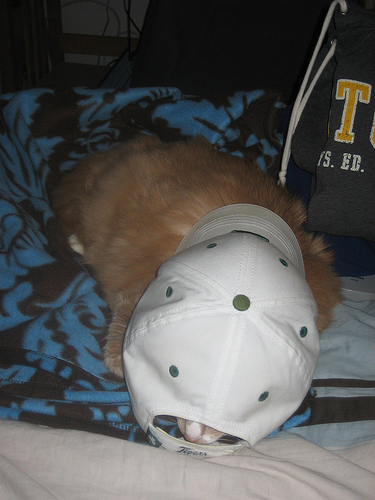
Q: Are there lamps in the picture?
A: No, there are no lamps.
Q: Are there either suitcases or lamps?
A: No, there are no lamps or suitcases.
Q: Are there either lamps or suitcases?
A: No, there are no lamps or suitcases.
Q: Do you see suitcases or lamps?
A: No, there are no lamps or suitcases.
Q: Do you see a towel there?
A: No, there are no towels.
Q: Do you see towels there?
A: No, there are no towels.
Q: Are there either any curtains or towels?
A: No, there are no towels or curtains.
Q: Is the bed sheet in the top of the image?
A: No, the bed sheet is in the bottom of the image.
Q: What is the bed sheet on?
A: The bed sheet is on the bed.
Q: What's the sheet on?
A: The bed sheet is on the bed.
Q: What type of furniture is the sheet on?
A: The sheet is on the bed.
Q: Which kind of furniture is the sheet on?
A: The sheet is on the bed.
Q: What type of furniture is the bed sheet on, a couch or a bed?
A: The bed sheet is on a bed.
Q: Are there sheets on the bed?
A: Yes, there is a sheet on the bed.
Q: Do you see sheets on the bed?
A: Yes, there is a sheet on the bed.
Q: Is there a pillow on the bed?
A: No, there is a sheet on the bed.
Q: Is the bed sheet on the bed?
A: Yes, the bed sheet is on the bed.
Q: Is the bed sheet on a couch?
A: No, the bed sheet is on the bed.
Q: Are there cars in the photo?
A: No, there are no cars.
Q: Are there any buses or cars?
A: No, there are no cars or buses.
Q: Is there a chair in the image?
A: No, there are no chairs.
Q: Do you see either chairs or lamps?
A: No, there are no chairs or lamps.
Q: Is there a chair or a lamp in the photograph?
A: No, there are no chairs or lamps.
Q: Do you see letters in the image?
A: Yes, there are letters.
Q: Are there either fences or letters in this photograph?
A: Yes, there are letters.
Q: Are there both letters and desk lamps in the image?
A: No, there are letters but no desk lamps.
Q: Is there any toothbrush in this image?
A: No, there are no toothbrushes.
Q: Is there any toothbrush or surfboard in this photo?
A: No, there are no toothbrushes or surfboards.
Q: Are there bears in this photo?
A: No, there are no bears.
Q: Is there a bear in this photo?
A: No, there are no bears.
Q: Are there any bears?
A: No, there are no bears.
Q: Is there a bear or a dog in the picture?
A: No, there are no bears or dogs.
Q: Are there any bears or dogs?
A: No, there are no bears or dogs.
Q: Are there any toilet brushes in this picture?
A: No, there are no toilet brushes.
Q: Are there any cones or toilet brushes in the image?
A: No, there are no toilet brushes or cones.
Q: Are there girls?
A: No, there are no girls.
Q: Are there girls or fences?
A: No, there are no girls or fences.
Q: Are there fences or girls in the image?
A: No, there are no girls or fences.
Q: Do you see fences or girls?
A: No, there are no girls or fences.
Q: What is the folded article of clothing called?
A: The clothing item is a shirt.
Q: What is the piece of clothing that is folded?
A: The clothing item is a shirt.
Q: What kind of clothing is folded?
A: The clothing is a shirt.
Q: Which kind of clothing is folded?
A: The clothing is a shirt.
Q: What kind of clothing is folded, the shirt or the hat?
A: The shirt is folded.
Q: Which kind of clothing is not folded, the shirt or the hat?
A: The hat is not folded.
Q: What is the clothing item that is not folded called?
A: The clothing item is a hat.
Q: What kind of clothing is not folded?
A: The clothing is a hat.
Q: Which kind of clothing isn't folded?
A: The clothing is a hat.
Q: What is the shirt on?
A: The shirt is on the bed.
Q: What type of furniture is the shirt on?
A: The shirt is on the bed.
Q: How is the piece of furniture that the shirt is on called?
A: The piece of furniture is a bed.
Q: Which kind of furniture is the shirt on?
A: The shirt is on the bed.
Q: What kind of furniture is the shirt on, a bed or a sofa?
A: The shirt is on a bed.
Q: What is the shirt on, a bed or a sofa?
A: The shirt is on a bed.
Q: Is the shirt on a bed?
A: Yes, the shirt is on a bed.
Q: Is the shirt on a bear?
A: No, the shirt is on a bed.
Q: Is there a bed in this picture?
A: Yes, there is a bed.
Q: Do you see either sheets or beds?
A: Yes, there is a bed.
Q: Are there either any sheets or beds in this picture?
A: Yes, there is a bed.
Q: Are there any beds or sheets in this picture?
A: Yes, there is a bed.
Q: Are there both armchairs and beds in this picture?
A: No, there is a bed but no armchairs.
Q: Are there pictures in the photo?
A: No, there are no pictures.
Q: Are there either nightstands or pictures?
A: No, there are no pictures or nightstands.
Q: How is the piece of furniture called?
A: The piece of furniture is a bed.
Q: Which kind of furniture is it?
A: The piece of furniture is a bed.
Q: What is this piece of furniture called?
A: This is a bed.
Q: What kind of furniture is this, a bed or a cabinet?
A: This is a bed.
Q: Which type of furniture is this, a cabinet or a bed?
A: This is a bed.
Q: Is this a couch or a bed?
A: This is a bed.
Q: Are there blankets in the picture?
A: Yes, there is a blanket.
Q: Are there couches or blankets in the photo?
A: Yes, there is a blanket.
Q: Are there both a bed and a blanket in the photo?
A: Yes, there are both a blanket and a bed.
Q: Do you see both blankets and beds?
A: Yes, there are both a blanket and a bed.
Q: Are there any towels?
A: No, there are no towels.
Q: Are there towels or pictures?
A: No, there are no towels or pictures.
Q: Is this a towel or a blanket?
A: This is a blanket.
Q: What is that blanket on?
A: The blanket is on the bed.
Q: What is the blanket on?
A: The blanket is on the bed.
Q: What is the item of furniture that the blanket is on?
A: The piece of furniture is a bed.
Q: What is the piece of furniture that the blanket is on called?
A: The piece of furniture is a bed.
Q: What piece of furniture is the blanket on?
A: The blanket is on the bed.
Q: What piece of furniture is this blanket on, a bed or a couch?
A: The blanket is on a bed.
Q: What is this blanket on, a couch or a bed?
A: The blanket is on a bed.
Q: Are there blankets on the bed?
A: Yes, there is a blanket on the bed.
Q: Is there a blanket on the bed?
A: Yes, there is a blanket on the bed.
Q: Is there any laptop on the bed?
A: No, there is a blanket on the bed.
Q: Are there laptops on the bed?
A: No, there is a blanket on the bed.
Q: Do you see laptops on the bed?
A: No, there is a blanket on the bed.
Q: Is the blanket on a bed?
A: Yes, the blanket is on a bed.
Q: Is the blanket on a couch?
A: No, the blanket is on a bed.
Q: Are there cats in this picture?
A: Yes, there is a cat.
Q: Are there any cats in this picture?
A: Yes, there is a cat.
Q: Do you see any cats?
A: Yes, there is a cat.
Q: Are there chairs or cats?
A: Yes, there is a cat.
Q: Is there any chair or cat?
A: Yes, there is a cat.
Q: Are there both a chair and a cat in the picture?
A: No, there is a cat but no chairs.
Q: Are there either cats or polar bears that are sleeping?
A: Yes, the cat is sleeping.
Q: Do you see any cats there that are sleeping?
A: Yes, there is a cat that is sleeping.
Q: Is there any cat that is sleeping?
A: Yes, there is a cat that is sleeping.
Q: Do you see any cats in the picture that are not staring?
A: Yes, there is a cat that is sleeping .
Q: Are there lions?
A: No, there are no lions.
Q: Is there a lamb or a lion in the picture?
A: No, there are no lions or lambs.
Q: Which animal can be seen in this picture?
A: The animal is a cat.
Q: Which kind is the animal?
A: The animal is a cat.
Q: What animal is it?
A: The animal is a cat.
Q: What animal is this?
A: This is a cat.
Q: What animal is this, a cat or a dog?
A: This is a cat.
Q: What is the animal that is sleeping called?
A: The animal is a cat.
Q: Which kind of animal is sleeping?
A: The animal is a cat.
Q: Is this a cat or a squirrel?
A: This is a cat.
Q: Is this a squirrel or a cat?
A: This is a cat.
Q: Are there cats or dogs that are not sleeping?
A: No, there is a cat but it is sleeping.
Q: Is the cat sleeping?
A: Yes, the cat is sleeping.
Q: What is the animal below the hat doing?
A: The cat is sleeping.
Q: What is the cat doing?
A: The cat is sleeping.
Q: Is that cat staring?
A: No, the cat is sleeping.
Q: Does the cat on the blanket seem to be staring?
A: No, the cat is sleeping.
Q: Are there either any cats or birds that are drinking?
A: No, there is a cat but it is sleeping.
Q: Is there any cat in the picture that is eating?
A: No, there is a cat but it is sleeping.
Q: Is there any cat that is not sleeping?
A: No, there is a cat but it is sleeping.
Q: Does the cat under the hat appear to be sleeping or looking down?
A: The cat is sleeping.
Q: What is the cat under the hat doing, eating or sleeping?
A: The cat is sleeping.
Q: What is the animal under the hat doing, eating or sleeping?
A: The cat is sleeping.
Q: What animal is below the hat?
A: The animal is a cat.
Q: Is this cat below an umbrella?
A: No, the cat is below the hat.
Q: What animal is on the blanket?
A: The cat is on the blanket.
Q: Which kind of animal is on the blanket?
A: The animal is a cat.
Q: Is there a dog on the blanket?
A: No, there is a cat on the blanket.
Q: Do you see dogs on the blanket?
A: No, there is a cat on the blanket.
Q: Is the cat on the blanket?
A: Yes, the cat is on the blanket.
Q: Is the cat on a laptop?
A: No, the cat is on the blanket.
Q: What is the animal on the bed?
A: The animal is a cat.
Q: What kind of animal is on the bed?
A: The animal is a cat.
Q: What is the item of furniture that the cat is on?
A: The piece of furniture is a bed.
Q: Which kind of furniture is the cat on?
A: The cat is on the bed.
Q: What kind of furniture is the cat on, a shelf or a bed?
A: The cat is on a bed.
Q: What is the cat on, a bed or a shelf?
A: The cat is on a bed.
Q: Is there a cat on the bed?
A: Yes, there is a cat on the bed.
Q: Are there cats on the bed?
A: Yes, there is a cat on the bed.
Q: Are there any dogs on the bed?
A: No, there is a cat on the bed.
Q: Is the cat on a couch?
A: No, the cat is on a bed.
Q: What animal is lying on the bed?
A: The cat is lying on the bed.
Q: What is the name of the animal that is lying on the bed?
A: The animal is a cat.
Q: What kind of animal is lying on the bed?
A: The animal is a cat.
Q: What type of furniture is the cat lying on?
A: The cat is lying on the bed.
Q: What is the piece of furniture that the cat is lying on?
A: The piece of furniture is a bed.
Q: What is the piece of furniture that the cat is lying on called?
A: The piece of furniture is a bed.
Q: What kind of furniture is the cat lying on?
A: The cat is lying on the bed.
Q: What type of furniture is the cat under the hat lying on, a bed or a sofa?
A: The cat is lying on a bed.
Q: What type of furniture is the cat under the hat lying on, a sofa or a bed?
A: The cat is lying on a bed.